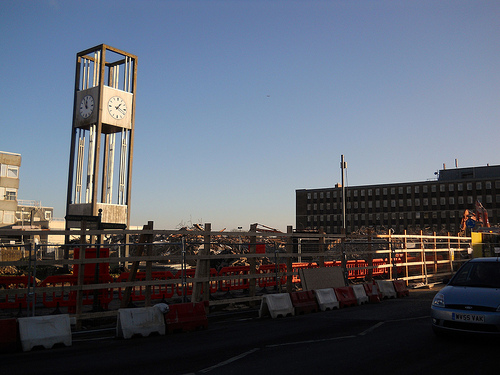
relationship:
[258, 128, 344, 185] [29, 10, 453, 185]
clouds in sky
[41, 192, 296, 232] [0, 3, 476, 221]
cloud in sky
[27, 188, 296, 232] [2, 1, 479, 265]
cloud in sky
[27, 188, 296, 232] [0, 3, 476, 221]
cloud in sky